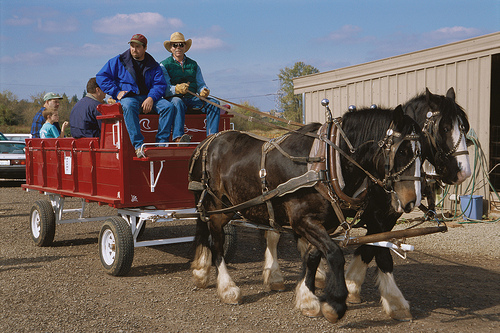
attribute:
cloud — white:
[95, 12, 192, 34]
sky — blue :
[191, 2, 497, 57]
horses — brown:
[184, 77, 484, 327]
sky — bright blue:
[2, 1, 499, 111]